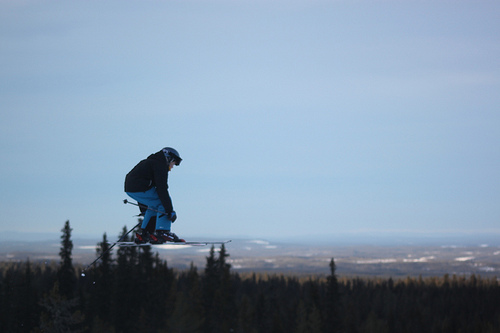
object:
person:
[123, 147, 187, 245]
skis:
[106, 240, 232, 247]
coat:
[124, 150, 173, 213]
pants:
[125, 187, 172, 231]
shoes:
[134, 232, 187, 245]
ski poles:
[87, 198, 168, 267]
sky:
[4, 2, 497, 243]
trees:
[41, 219, 338, 332]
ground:
[231, 244, 500, 279]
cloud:
[440, 41, 492, 94]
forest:
[0, 221, 499, 333]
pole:
[82, 220, 144, 272]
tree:
[45, 220, 93, 332]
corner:
[30, 318, 35, 323]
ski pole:
[123, 198, 169, 218]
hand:
[158, 208, 178, 222]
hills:
[0, 237, 499, 281]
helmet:
[162, 147, 183, 171]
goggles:
[165, 151, 183, 166]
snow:
[365, 257, 429, 264]